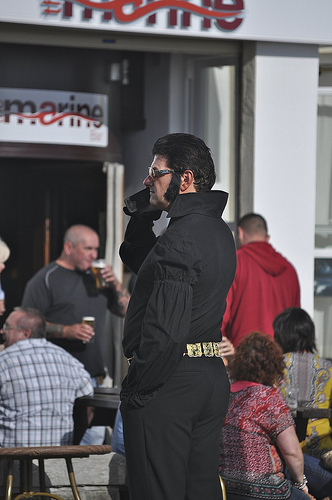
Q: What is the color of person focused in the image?
A: Black.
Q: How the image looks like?
A: Good.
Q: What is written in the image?
A: Marine.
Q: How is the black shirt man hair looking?
A: Good and very long.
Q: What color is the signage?
A: Red and white.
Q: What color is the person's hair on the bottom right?
A: Brown.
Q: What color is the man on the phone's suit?
A: Black.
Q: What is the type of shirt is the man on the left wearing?
A: Plaid.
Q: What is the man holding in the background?
A: Beer.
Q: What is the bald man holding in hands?
A: Glasses of beer.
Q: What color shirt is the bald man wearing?
A: Grey.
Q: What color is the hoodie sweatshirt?
A: Red.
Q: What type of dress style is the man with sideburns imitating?
A: Elvis.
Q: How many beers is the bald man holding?
A: Two.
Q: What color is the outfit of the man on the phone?
A: Black.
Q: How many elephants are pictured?
A: Zero.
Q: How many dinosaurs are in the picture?
A: Zero.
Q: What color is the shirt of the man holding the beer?
A: Black.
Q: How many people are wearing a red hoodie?
A: One.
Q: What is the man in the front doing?
A: Talking on a phone.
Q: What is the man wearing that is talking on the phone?
A: A black jumpsuit.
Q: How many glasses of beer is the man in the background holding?
A: Two.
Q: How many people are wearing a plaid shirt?
A: One.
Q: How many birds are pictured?
A: Zero.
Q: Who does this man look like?
A: Elvis.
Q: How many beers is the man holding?
A: 2.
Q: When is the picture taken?
A: Daytime.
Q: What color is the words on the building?
A: Red.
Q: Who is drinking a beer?
A: A man.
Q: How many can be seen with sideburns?
A: 1.